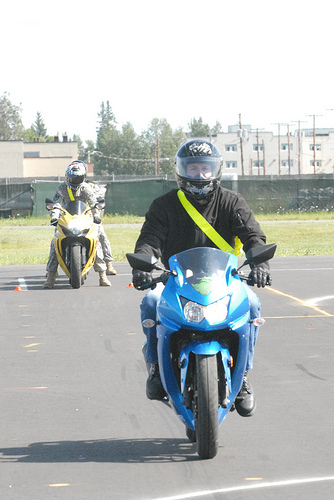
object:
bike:
[126, 242, 277, 460]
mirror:
[245, 242, 277, 266]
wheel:
[195, 354, 219, 461]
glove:
[247, 260, 272, 287]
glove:
[132, 267, 157, 291]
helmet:
[174, 139, 223, 202]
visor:
[173, 156, 222, 180]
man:
[43, 160, 112, 289]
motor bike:
[44, 196, 106, 289]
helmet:
[64, 160, 86, 191]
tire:
[70, 243, 81, 289]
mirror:
[45, 197, 54, 203]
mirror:
[96, 195, 105, 203]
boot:
[146, 363, 169, 401]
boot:
[235, 372, 257, 418]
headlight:
[183, 300, 204, 324]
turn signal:
[142, 319, 156, 329]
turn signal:
[253, 318, 265, 327]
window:
[225, 144, 237, 152]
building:
[184, 113, 334, 174]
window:
[226, 161, 237, 169]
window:
[253, 144, 264, 151]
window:
[253, 160, 263, 167]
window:
[281, 142, 293, 151]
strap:
[176, 188, 244, 257]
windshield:
[176, 246, 231, 295]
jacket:
[133, 188, 270, 271]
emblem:
[189, 141, 212, 156]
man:
[131, 136, 273, 418]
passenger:
[45, 159, 117, 277]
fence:
[0, 173, 334, 217]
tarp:
[0, 175, 334, 217]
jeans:
[140, 278, 265, 373]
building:
[0, 140, 79, 177]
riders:
[40, 155, 113, 291]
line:
[263, 283, 332, 316]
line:
[259, 313, 332, 320]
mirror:
[125, 252, 158, 272]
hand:
[132, 267, 157, 290]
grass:
[0, 209, 334, 266]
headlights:
[184, 295, 231, 325]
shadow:
[0, 438, 202, 465]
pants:
[46, 223, 108, 273]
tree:
[93, 100, 121, 176]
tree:
[137, 117, 175, 175]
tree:
[185, 116, 223, 137]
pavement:
[0, 252, 334, 500]